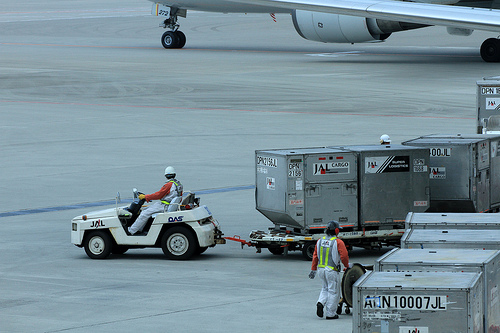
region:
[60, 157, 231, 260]
man in white truck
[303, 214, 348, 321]
man in white pants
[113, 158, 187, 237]
men wearing hat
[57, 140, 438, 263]
silver containers attached to white truck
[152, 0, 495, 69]
plane is white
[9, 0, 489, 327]
blue line on road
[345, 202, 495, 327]
number N100074 on silver tank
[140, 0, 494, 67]
airplane has black wheels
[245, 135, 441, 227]
silver tank with written on the side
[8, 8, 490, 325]
road is gray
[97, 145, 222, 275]
a man driving a car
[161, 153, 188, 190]
a man wearing a helmet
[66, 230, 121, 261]
the wheel of a car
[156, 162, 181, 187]
the head of a man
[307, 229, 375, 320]
a man wearing pants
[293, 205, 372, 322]
a man wearing shoes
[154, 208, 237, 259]
the back wheel of a car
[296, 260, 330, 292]
the hand of a man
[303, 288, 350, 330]
a man wearing black shoes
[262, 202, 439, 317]
a man at a airport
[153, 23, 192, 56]
Wheels of a plane.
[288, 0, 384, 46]
Engine on the plane.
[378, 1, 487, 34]
Part of a wing on the plane.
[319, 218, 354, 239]
Wearing headphones for protection.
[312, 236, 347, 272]
Man wearing a safety vest.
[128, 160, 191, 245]
Driver towing luggage from the plane.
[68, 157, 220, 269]
Man riding in white cart.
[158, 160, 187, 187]
Man wearing a white hard hat.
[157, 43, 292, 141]
Grey cement where the plane is parked.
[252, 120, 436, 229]
Silver boxes filled with cargo.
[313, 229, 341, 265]
worker wearing a safety vest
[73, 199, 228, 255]
cart pulling canisters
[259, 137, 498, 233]
canisters are silver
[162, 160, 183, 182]
worker wearing a hard hat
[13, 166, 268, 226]
blue line on the ground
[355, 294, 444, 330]
stickers on the canisters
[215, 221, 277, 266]
red hook to the cart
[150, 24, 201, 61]
wheels of the airplane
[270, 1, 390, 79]
engine on the plane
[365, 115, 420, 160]
person behind the canisters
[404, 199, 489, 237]
grey metal cargo container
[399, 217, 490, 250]
grey metal cargo container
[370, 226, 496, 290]
grey metal cargo container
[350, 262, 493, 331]
grey metal cargo container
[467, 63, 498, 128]
grey metal cargo container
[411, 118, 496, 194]
grey metal cargo container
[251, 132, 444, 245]
grey metal cargo container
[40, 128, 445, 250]
person pulling metal container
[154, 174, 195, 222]
person wearing neon vest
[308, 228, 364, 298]
person wearing neon vest